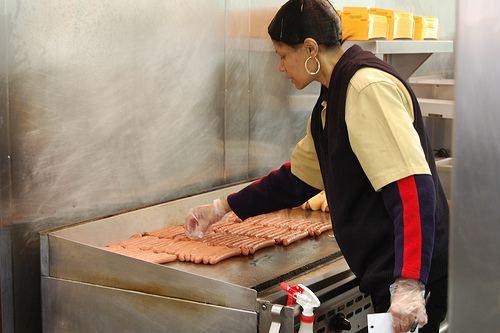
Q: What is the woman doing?
A: Cooking.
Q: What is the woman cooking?
A: Hot dogs.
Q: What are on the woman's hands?
A: Plastic gloves.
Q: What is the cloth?
A: This is a vest.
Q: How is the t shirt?
A: Yellow color.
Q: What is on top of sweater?
A: Brown color sweater.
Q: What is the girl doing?
A: Arranging hot dogs.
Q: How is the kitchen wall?
A: Silver colored metal wall.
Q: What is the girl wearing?
A: A black vest.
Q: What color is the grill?
A: Silver.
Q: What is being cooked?
A: Hot Dogs.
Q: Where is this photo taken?
A: Kitchen.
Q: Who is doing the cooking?
A: Woman.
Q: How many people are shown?
A: One.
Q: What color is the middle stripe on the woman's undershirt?
A: Red.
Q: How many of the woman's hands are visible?
A: Two.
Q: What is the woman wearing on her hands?
A: Gloves.